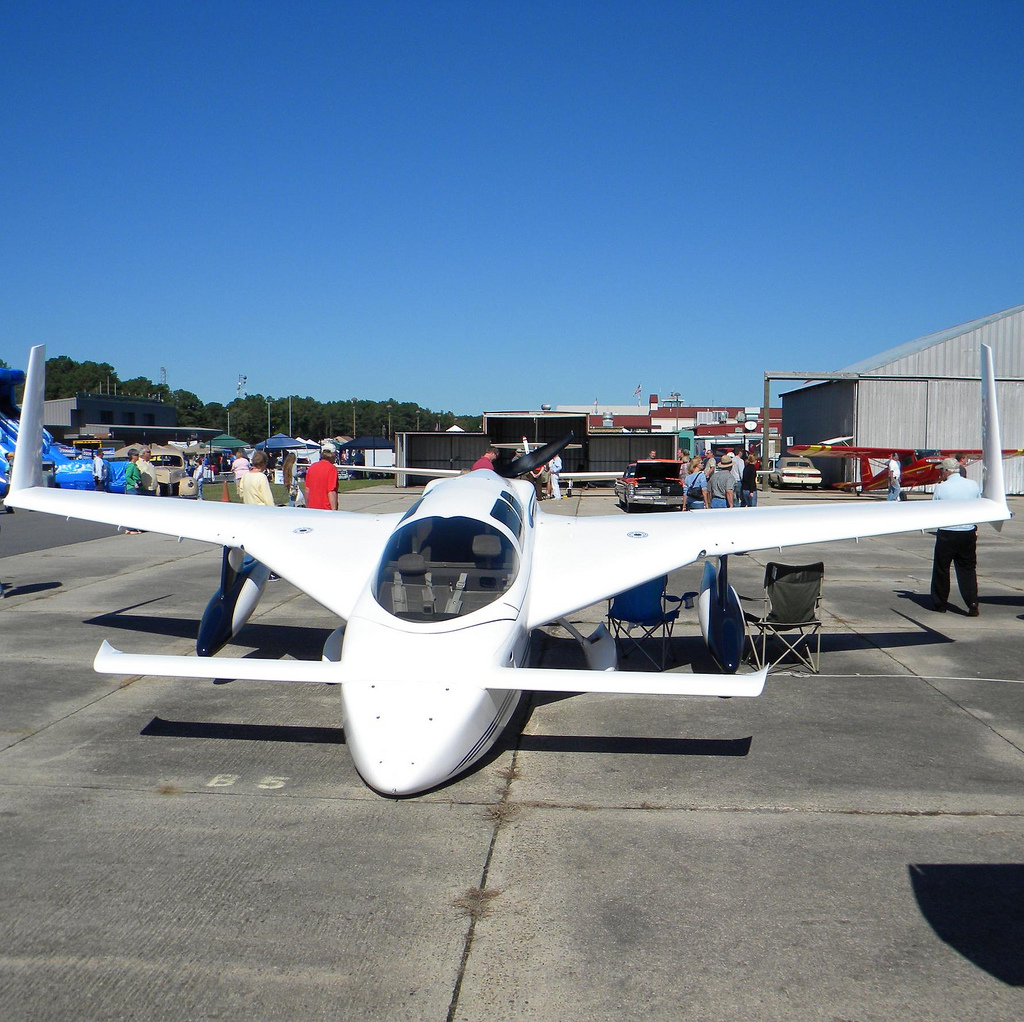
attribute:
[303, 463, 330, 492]
shirt — red, short sleeve 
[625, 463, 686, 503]
car — old , red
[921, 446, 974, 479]
hat — brown, black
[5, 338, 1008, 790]
plane — small, red, yellow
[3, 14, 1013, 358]
sky — large, blue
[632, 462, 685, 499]
bonnet —  open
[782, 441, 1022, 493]
aircraft — red